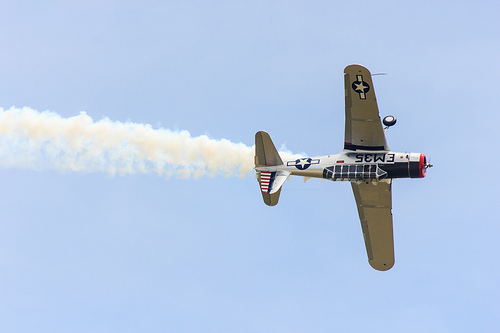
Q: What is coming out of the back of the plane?
A: A trail of exhaust.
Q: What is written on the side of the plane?
A: EM35.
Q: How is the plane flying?
A: Upside down.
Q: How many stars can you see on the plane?
A: Two.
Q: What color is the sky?
A: Blue.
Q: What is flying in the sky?
A: Airplane.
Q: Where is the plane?
A: Air.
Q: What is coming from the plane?
A: Smoke.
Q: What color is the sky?
A: Blue.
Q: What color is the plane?
A: Red, white and blue.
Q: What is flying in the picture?
A: Airplane.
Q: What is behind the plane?
A: Smoke.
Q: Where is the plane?
A: In the sky.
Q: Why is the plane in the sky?
A: It flies.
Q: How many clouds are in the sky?
A: None.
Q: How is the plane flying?
A: Upside down.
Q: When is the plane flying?
A: Daytime.